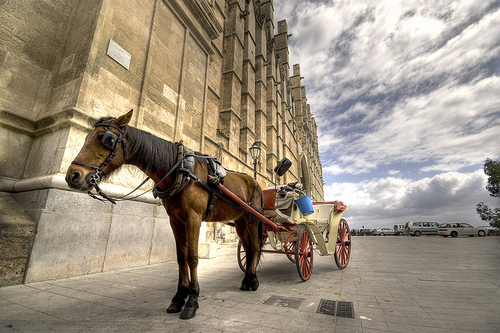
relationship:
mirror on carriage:
[272, 157, 294, 182] [235, 157, 352, 282]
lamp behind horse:
[248, 141, 261, 179] [64, 108, 263, 318]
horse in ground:
[64, 108, 263, 318] [0, 232, 499, 331]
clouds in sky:
[332, 42, 470, 171] [306, 2, 496, 209]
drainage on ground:
[313, 292, 360, 324] [244, 269, 444, 330]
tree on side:
[472, 160, 498, 224] [466, 134, 498, 250]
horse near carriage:
[64, 108, 264, 319] [262, 179, 350, 278]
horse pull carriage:
[64, 108, 263, 318] [235, 157, 352, 282]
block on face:
[98, 130, 122, 150] [60, 108, 137, 195]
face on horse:
[60, 108, 137, 195] [64, 108, 263, 318]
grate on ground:
[315, 296, 355, 319] [0, 232, 499, 331]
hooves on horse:
[166, 290, 198, 317] [64, 108, 263, 318]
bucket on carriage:
[291, 191, 317, 221] [235, 157, 352, 282]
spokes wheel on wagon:
[295, 230, 314, 281] [235, 182, 352, 282]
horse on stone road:
[64, 108, 263, 318] [4, 223, 495, 331]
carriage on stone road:
[253, 161, 360, 274] [4, 223, 495, 331]